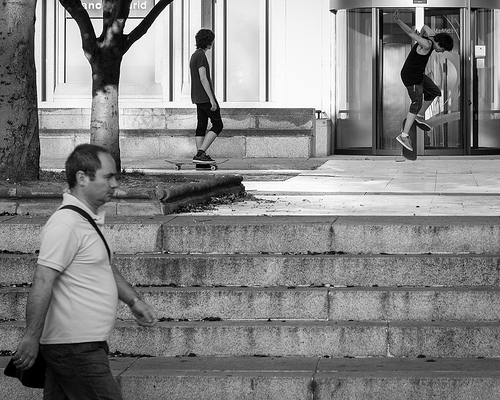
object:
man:
[8, 143, 158, 399]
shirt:
[35, 193, 118, 345]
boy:
[392, 9, 455, 151]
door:
[371, 3, 471, 156]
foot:
[395, 132, 413, 152]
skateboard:
[401, 117, 417, 161]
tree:
[59, 0, 173, 175]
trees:
[0, 1, 41, 183]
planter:
[2, 171, 245, 215]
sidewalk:
[186, 158, 500, 217]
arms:
[394, 19, 429, 47]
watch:
[126, 294, 142, 308]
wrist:
[126, 291, 146, 307]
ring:
[19, 357, 23, 362]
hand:
[10, 334, 40, 372]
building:
[172, 5, 394, 155]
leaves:
[218, 197, 229, 201]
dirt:
[265, 199, 277, 203]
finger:
[20, 358, 37, 372]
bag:
[4, 205, 111, 389]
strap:
[54, 205, 112, 268]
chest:
[71, 231, 113, 270]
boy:
[189, 28, 224, 170]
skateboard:
[164, 158, 230, 171]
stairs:
[272, 320, 426, 358]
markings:
[135, 257, 185, 284]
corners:
[159, 173, 246, 214]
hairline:
[95, 149, 112, 168]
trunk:
[89, 65, 121, 171]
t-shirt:
[189, 49, 215, 104]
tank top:
[400, 37, 434, 88]